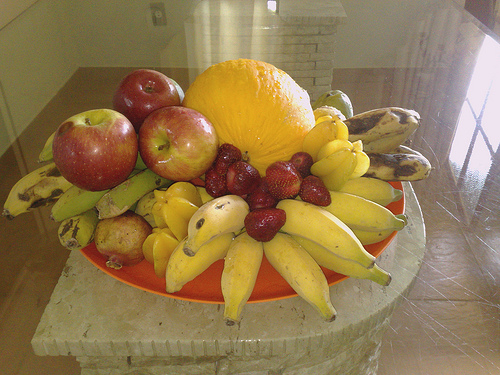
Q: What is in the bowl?
A: Fruit.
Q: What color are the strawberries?
A: Red.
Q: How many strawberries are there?
A: Eight.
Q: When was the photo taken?
A: Daytime.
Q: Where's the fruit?
A: In a bowl.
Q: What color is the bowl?
A: Orange.